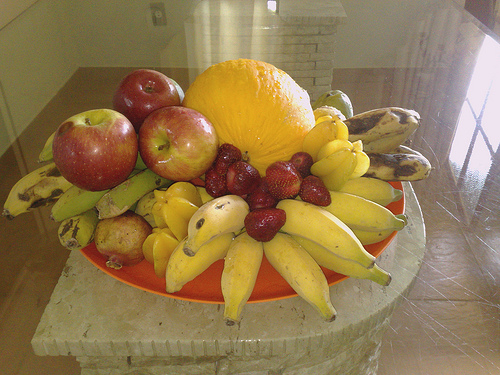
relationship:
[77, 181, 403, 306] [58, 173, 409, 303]
bowl on a platter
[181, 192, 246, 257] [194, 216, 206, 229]
banana with mark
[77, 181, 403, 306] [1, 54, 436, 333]
bowl of fruits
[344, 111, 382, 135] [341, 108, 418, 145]
mark on a fruit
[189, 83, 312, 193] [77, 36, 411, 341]
orange in bowl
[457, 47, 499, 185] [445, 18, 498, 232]
sunlight coming thru window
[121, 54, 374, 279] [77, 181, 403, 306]
fruit arranged on a bowl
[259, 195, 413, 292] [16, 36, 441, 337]
bananas in a fruit fruit arrangement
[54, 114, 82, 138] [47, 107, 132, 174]
spot on apple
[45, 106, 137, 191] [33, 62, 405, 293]
apple on pile of fruit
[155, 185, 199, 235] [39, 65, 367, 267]
starfruit in pile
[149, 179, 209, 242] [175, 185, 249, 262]
starfruit in pile of fruit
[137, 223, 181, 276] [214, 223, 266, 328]
starfruit in pile of fruit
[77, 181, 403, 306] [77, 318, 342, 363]
bowl on a table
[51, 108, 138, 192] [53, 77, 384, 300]
apple on  a fruit arrangement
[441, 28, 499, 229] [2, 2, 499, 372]
windows in building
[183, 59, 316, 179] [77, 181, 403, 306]
orange in bowl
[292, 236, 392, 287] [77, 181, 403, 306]
bananas in bowl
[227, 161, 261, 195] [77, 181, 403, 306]
strawberries in bowl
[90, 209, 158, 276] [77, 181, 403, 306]
pomegranate in bowl